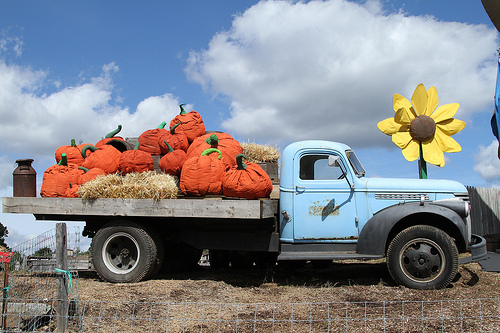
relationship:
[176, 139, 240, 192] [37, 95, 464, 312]
pumpkin on truck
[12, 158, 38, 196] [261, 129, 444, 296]
bucket on truck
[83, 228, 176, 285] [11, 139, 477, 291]
wheel on truck